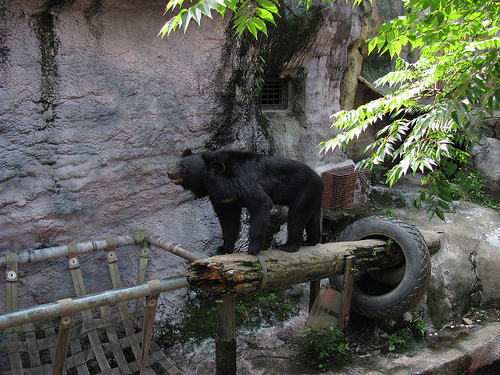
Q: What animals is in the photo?
A: A bear.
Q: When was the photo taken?
A: Day time.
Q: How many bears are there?
A: One.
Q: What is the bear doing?
A: Walking.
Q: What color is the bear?
A: Black.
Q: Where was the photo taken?
A: In a zoo.